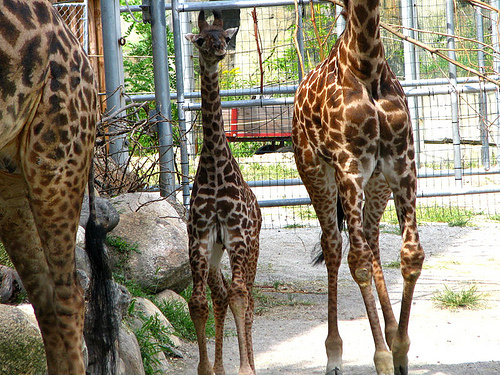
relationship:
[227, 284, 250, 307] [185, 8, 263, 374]
knee of giraffe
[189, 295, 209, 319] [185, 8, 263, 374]
knee of giraffe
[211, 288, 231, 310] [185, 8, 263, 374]
knee of giraffe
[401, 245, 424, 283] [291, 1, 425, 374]
knee of giraffe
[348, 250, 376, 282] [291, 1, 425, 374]
knee of giraffe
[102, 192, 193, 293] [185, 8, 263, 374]
stone next to giraffe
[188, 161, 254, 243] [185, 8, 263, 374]
chest of giraffe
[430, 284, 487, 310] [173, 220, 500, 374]
grass on ground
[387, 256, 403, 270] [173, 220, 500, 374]
grass on ground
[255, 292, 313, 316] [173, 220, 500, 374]
grass on ground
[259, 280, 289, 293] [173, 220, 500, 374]
grass on ground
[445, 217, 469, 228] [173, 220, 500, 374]
grass on ground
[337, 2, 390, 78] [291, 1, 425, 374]
neck of giraffe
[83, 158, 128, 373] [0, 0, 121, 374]
tail of giraffe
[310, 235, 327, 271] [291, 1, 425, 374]
tail of giraffe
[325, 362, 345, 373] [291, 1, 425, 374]
hoof on giraffe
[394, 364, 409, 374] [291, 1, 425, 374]
hoof on giraffe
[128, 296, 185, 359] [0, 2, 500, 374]
rock in enclosure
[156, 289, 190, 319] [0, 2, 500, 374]
rock in enclosure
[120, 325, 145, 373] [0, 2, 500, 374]
rock in enclosure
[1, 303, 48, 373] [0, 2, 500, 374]
rock in enclosure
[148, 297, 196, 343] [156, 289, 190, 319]
vegetation on rock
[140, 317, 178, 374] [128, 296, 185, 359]
vegetation on rock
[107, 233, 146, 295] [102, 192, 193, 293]
vegetation on rock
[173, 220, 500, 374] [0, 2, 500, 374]
ground in enclosure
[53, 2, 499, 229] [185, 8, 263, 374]
fence behind giraffe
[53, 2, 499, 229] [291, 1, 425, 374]
fence behind giraffe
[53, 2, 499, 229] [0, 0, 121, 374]
fence behind giraffe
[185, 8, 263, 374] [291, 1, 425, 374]
giraffe next to giraffe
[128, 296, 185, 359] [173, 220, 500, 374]
rock on ground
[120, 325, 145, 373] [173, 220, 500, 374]
rock on ground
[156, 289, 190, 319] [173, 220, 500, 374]
rock on ground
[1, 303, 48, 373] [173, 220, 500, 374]
rock on ground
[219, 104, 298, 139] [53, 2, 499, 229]
crate behind fence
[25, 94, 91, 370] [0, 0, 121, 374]
leg of giraffe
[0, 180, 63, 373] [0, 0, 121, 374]
leg of giraffe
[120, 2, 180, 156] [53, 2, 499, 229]
tree behind fence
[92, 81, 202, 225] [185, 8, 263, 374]
branches next to giraffe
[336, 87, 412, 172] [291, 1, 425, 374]
chest of giraffe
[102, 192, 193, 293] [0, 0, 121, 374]
stone behind giraffe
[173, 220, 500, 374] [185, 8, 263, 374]
ground under giraffe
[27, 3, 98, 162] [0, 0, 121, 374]
hip of giraffe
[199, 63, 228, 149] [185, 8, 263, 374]
neck of giraffe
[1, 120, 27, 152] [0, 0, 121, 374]
stomach of giraffe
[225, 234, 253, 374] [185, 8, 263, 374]
leg of giraffe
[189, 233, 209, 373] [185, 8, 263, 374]
leg of giraffe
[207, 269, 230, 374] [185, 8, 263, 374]
leg of giraffe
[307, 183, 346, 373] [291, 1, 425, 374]
leg of giraffe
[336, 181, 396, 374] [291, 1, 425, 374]
leg of giraffe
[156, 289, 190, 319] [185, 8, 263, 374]
rock beside giraffe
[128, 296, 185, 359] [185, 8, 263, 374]
rock beside giraffe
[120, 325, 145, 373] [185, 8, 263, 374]
rock beside giraffe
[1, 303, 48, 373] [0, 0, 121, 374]
rock beside giraffe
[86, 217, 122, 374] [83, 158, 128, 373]
hair on tail